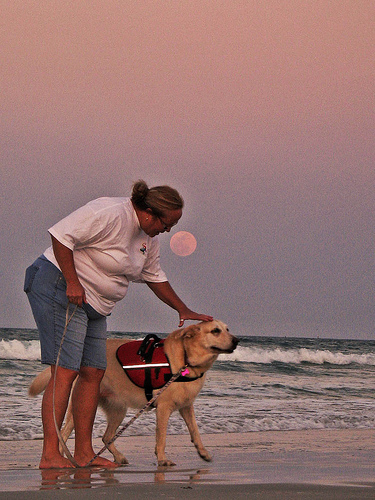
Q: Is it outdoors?
A: Yes, it is outdoors.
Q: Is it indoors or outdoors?
A: It is outdoors.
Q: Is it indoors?
A: No, it is outdoors.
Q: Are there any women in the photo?
A: Yes, there is a woman.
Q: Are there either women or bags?
A: Yes, there is a woman.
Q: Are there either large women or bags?
A: Yes, there is a large woman.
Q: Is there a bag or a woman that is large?
A: Yes, the woman is large.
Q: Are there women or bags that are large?
A: Yes, the woman is large.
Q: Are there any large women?
A: Yes, there is a large woman.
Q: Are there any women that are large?
A: Yes, there is a woman that is large.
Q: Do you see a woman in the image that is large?
A: Yes, there is a woman that is large.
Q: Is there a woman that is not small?
A: Yes, there is a large woman.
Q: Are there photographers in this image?
A: No, there are no photographers.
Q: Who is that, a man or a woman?
A: That is a woman.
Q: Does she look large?
A: Yes, the woman is large.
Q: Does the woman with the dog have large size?
A: Yes, the woman is large.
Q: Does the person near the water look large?
A: Yes, the woman is large.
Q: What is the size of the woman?
A: The woman is large.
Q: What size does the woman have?
A: The woman has large size.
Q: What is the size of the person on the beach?
A: The woman is large.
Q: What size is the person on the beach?
A: The woman is large.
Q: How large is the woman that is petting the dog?
A: The woman is large.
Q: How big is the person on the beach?
A: The woman is large.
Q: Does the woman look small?
A: No, the woman is large.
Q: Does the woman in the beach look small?
A: No, the woman is large.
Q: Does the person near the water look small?
A: No, the woman is large.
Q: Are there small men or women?
A: No, there is a woman but she is large.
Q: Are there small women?
A: No, there is a woman but she is large.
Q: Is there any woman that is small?
A: No, there is a woman but she is large.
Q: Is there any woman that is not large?
A: No, there is a woman but she is large.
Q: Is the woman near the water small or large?
A: The woman is large.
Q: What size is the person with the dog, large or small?
A: The woman is large.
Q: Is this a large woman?
A: Yes, this is a large woman.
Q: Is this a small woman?
A: No, this is a large woman.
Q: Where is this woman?
A: The woman is on the beach.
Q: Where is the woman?
A: The woman is on the beach.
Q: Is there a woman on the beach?
A: Yes, there is a woman on the beach.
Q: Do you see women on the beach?
A: Yes, there is a woman on the beach.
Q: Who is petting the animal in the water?
A: The woman is petting the dog.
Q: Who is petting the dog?
A: The woman is petting the dog.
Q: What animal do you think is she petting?
A: The woman is petting the dog.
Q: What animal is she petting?
A: The woman is petting the dog.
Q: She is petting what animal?
A: The woman is petting the dog.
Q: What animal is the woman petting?
A: The woman is petting the dog.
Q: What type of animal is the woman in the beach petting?
A: The woman is petting the dog.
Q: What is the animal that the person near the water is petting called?
A: The animal is a dog.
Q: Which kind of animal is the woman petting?
A: The woman is petting the dog.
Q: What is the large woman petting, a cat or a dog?
A: The woman is petting a dog.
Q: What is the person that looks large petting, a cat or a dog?
A: The woman is petting a dog.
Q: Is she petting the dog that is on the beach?
A: Yes, the woman is petting the dog.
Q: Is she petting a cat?
A: No, the woman is petting the dog.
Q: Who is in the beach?
A: The woman is in the beach.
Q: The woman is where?
A: The woman is in the beach.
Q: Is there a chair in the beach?
A: No, there is a woman in the beach.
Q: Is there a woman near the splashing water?
A: Yes, there is a woman near the water.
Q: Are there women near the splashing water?
A: Yes, there is a woman near the water.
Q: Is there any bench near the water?
A: No, there is a woman near the water.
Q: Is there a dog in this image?
A: Yes, there is a dog.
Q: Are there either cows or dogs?
A: Yes, there is a dog.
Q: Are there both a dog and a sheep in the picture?
A: No, there is a dog but no sheep.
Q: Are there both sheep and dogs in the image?
A: No, there is a dog but no sheep.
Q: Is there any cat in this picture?
A: No, there are no cats.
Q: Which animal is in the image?
A: The animal is a dog.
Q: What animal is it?
A: The animal is a dog.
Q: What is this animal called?
A: That is a dog.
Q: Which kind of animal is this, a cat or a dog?
A: That is a dog.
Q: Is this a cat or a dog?
A: This is a dog.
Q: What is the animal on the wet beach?
A: The animal is a dog.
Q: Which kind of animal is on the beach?
A: The animal is a dog.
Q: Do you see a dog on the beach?
A: Yes, there is a dog on the beach.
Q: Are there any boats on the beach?
A: No, there is a dog on the beach.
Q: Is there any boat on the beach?
A: No, there is a dog on the beach.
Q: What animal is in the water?
A: The dog is in the water.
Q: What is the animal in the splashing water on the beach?
A: The animal is a dog.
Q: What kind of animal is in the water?
A: The animal is a dog.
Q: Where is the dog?
A: The dog is in the water.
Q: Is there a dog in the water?
A: Yes, there is a dog in the water.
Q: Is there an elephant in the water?
A: No, there is a dog in the water.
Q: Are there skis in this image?
A: No, there are no skis.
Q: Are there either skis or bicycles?
A: No, there are no skis or bicycles.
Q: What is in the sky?
A: The moon is in the sky.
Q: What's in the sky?
A: The moon is in the sky.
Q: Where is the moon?
A: The moon is in the sky.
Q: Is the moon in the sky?
A: Yes, the moon is in the sky.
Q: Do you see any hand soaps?
A: No, there are no hand soaps.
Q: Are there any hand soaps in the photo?
A: No, there are no hand soaps.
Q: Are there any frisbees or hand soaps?
A: No, there are no hand soaps or frisbees.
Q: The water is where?
A: The water is on the beach.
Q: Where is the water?
A: The water is on the beach.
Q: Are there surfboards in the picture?
A: No, there are no surfboards.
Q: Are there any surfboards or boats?
A: No, there are no surfboards or boats.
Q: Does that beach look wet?
A: Yes, the beach is wet.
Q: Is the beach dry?
A: No, the beach is wet.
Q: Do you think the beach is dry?
A: No, the beach is wet.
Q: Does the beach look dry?
A: No, the beach is wet.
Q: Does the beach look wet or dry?
A: The beach is wet.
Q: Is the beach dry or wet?
A: The beach is wet.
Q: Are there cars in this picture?
A: No, there are no cars.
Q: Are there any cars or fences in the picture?
A: No, there are no cars or fences.